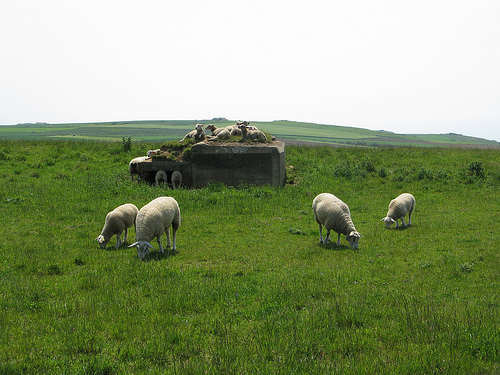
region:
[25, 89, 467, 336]
Multiple sheep lounging around in a field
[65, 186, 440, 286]
Four sheep grazing in a field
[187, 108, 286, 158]
Multiple sheep on a concrete structure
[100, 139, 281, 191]
A large concrete structure in a field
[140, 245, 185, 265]
Shadow of a sheep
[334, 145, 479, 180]
Small plants grow near the structure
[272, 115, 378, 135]
Trees in the distance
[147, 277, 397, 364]
The grass is tall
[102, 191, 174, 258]
The sheep are white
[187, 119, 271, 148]
The sheep are resting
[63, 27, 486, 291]
picture taken outdoors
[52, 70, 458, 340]
picture taken during the day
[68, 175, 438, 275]
sheep are grazing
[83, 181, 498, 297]
the sheep are on grass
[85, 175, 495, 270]
Four sheep on the land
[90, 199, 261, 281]
the sheep have two ears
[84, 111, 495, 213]
the mountains are behind the sheep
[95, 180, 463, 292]
the sheep are white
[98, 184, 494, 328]
the sheep have been shaved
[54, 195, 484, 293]
all four sheep are eating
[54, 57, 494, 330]
sheep in a field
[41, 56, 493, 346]
sheep in a grass field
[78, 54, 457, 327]
sheep from green grass field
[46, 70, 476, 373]
field with sheep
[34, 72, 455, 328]
sheep eating the grass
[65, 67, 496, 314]
sheep eating in the field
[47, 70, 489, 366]
sheep eating the green grass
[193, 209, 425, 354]
a field of green grass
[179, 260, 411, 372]
a field of grass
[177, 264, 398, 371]
a field with tall grass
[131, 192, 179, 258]
a white sheep grazing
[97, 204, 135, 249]
a white sheep grazing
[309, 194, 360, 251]
a white sheep grazing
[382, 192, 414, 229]
a white sheep grazing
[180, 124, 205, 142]
a white sheep resting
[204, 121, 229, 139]
a white sheep resting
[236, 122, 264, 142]
a white sheep resting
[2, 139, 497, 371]
a green grass pasture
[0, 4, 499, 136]
a hazy white sky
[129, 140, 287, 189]
a large concrete bunker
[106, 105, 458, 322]
Sheep grazing in a field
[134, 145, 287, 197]
A large cement structure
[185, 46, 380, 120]
A blindingly bright sky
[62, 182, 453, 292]
Four sheep in a field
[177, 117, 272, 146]
Multiple sheep resting together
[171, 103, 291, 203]
Sheep on top of the structure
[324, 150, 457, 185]
Small green plants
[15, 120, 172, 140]
Farm plots in the distance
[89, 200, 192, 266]
The sheep have their heads down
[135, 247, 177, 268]
Shadow of the sheep